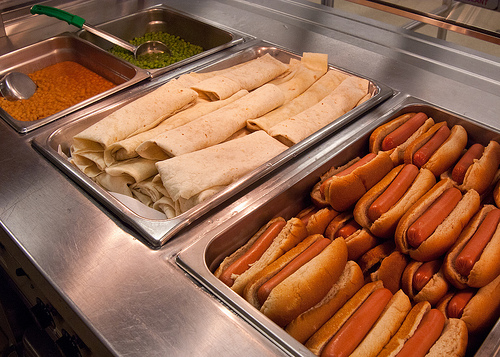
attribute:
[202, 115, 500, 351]
hotdogs — close, cooked, yellow, brown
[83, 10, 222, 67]
peas — folded, close, plain, glass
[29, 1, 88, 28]
handle — green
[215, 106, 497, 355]
buns — white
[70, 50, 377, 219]
food — hot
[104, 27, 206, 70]
peas — hot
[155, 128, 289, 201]
burrito — big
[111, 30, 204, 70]
peas — green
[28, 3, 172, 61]
serving spoon — large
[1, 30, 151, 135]
tray — metallic, small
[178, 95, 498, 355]
tray — large, metallic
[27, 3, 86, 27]
handle — green, long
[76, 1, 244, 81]
tray — metallic, small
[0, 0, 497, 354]
counter — metallic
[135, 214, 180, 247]
corner — rounded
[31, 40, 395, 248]
tray — metallic, large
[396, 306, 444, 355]
hot dog — plain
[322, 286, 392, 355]
hot dog — plain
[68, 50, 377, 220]
burritos — rolled, white, close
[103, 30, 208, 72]
peas — olive-green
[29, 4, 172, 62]
spoon — metallic, large, metal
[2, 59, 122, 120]
beans — baked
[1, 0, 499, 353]
buffet — hot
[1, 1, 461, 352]
table — buffet, stainless steel, buffet table, large, metallic